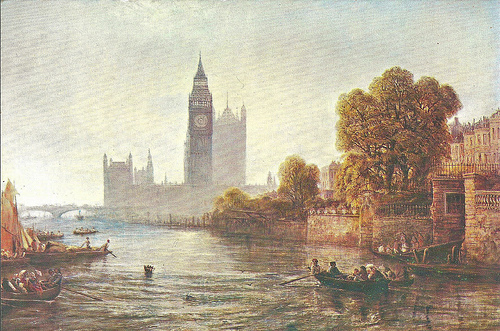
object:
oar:
[54, 283, 104, 301]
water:
[0, 217, 500, 331]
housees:
[471, 113, 492, 168]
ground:
[404, 260, 500, 284]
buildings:
[132, 147, 155, 186]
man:
[311, 257, 327, 276]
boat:
[365, 234, 469, 263]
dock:
[406, 240, 500, 285]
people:
[399, 231, 410, 253]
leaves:
[395, 112, 420, 154]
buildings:
[424, 106, 500, 178]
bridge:
[16, 203, 109, 221]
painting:
[2, 2, 496, 323]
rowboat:
[307, 265, 393, 296]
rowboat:
[388, 272, 416, 288]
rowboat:
[0, 282, 63, 303]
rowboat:
[13, 248, 114, 261]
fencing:
[427, 155, 499, 180]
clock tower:
[184, 50, 215, 188]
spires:
[193, 50, 208, 80]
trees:
[327, 61, 465, 216]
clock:
[193, 114, 209, 128]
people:
[98, 238, 110, 251]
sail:
[0, 177, 36, 259]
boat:
[0, 253, 32, 267]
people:
[327, 261, 345, 280]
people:
[347, 267, 360, 281]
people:
[353, 266, 368, 282]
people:
[365, 263, 387, 282]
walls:
[370, 214, 434, 256]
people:
[48, 267, 63, 287]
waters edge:
[225, 233, 361, 249]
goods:
[48, 245, 64, 253]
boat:
[71, 226, 100, 237]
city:
[104, 50, 284, 220]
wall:
[303, 205, 364, 249]